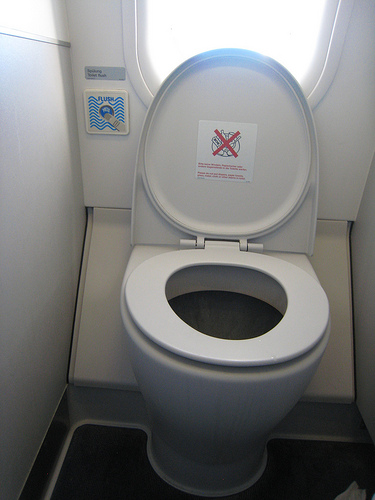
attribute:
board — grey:
[54, 378, 370, 499]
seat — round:
[261, 332, 294, 370]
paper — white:
[337, 475, 366, 495]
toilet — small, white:
[109, 247, 332, 425]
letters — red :
[214, 128, 239, 155]